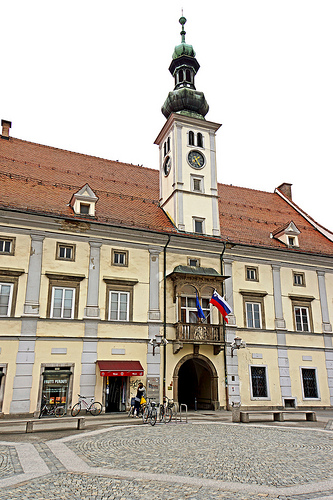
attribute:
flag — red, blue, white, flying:
[214, 291, 230, 318]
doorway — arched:
[173, 348, 224, 415]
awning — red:
[101, 360, 142, 375]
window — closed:
[112, 292, 126, 322]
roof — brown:
[2, 158, 292, 219]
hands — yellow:
[194, 155, 203, 163]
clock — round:
[187, 150, 206, 171]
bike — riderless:
[136, 401, 157, 426]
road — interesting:
[7, 423, 332, 494]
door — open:
[101, 377, 129, 407]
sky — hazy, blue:
[1, 5, 332, 193]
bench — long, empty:
[240, 403, 314, 422]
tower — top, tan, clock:
[164, 30, 214, 235]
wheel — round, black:
[149, 412, 159, 424]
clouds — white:
[251, 48, 304, 104]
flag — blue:
[187, 292, 206, 322]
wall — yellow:
[1, 227, 324, 400]